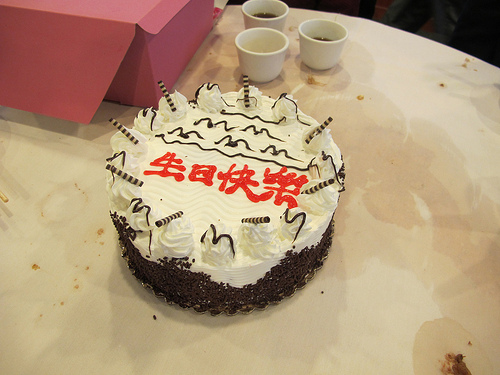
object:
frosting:
[143, 152, 309, 210]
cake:
[105, 74, 347, 317]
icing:
[155, 109, 320, 176]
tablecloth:
[0, 3, 500, 373]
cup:
[297, 19, 349, 71]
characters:
[144, 152, 310, 209]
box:
[0, 1, 214, 126]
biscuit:
[243, 75, 249, 108]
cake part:
[115, 214, 337, 316]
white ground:
[2, 0, 499, 372]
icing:
[105, 85, 346, 315]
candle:
[155, 211, 182, 228]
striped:
[324, 121, 329, 126]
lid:
[1, 0, 192, 125]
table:
[3, 0, 498, 373]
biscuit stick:
[242, 216, 270, 223]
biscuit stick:
[155, 211, 183, 227]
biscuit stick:
[105, 164, 144, 187]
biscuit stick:
[109, 117, 140, 144]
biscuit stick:
[158, 80, 177, 112]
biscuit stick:
[242, 75, 249, 107]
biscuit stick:
[300, 179, 335, 194]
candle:
[301, 179, 335, 195]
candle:
[305, 116, 333, 143]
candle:
[243, 75, 251, 107]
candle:
[157, 80, 176, 112]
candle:
[108, 117, 138, 145]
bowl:
[234, 27, 289, 83]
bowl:
[241, 0, 288, 33]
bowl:
[298, 18, 348, 70]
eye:
[236, 30, 286, 53]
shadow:
[0, 0, 500, 374]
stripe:
[106, 164, 111, 171]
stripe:
[110, 165, 115, 172]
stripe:
[114, 168, 120, 175]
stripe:
[125, 174, 131, 181]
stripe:
[135, 180, 142, 186]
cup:
[234, 27, 287, 83]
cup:
[242, 0, 289, 33]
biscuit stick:
[305, 116, 333, 144]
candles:
[105, 164, 144, 188]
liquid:
[313, 37, 333, 40]